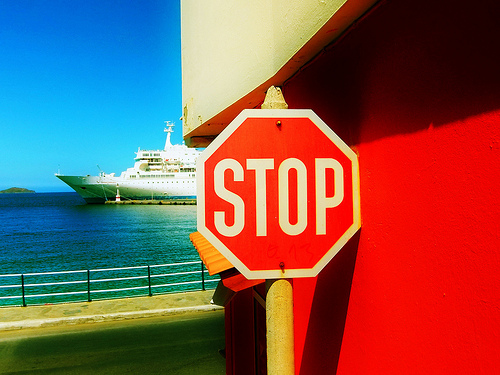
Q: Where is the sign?
A: On a post.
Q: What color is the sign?
A: Red.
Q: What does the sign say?
A: Stop.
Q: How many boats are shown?
A: One.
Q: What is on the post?
A: A sign.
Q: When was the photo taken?
A: Daytime.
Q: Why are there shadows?
A: It is sunny.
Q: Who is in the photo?
A: Nobody.